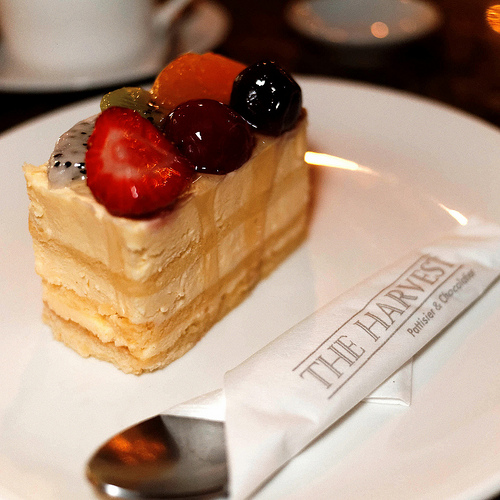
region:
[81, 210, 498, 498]
The silver spoon is next to the dessert.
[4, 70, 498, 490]
The dessert is on the white plate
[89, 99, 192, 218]
There are strawberries on top of the dessert.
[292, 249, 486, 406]
The Harvest is the name of the restaraunt.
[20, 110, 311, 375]
The dessert is made from ice cream.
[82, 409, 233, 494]
The bowl of the spoon is silver.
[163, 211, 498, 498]
The napkin is white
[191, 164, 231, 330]
The is fruit juices running down the side of the dessert.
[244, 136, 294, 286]
There are fruit juices running down the side of the dessert.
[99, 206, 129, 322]
There are fruit juices running down the side of the dessert.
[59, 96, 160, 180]
The kiwi on the piece of cake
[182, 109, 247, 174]
The cherry on the piece of cake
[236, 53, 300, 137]
The blue berry on the piece of cake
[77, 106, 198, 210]
The strawberry on the piece of cake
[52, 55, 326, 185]
The mixed fruit on the piece of cake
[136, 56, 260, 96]
The piece of orange on the cake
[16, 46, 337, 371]
A piece of cake with the fruit on it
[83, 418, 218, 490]
The tip of the spooon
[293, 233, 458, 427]
The label on the napkins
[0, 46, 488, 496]
A white plate with the cake and spoon on it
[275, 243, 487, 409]
Resturant logo on the napkin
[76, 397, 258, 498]
spoon wrapped in the white napkin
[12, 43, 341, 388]
Mini piece of dessert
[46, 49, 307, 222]
Fruit on top of the dessert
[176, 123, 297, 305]
Liquid dripping down the dessert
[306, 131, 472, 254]
Light shining off the plate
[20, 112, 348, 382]
Dessert is in layers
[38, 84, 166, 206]
Kiwi slices on top of the dessert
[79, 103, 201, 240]
a cut strawberry on the dessert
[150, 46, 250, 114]
A Juicy slice of an mardarin orange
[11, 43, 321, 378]
fruit on the cake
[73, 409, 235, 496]
head of the spoon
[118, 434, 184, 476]
reflection in the spoon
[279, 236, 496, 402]
words on the napkin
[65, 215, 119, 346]
layers on the cake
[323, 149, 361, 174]
shiny spot on the plate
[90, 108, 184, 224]
strawberry on the cake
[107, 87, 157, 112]
kiwi on the cake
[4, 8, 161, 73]
coffee mug in the background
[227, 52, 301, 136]
black raspberry on the cake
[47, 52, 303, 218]
the pieces of various fruit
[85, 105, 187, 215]
the piece of strawberry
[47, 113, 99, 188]
the piece of dragonfruit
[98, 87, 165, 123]
the piece of kiwi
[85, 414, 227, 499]
the top of the spoon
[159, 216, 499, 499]
the napkin wrapped around the spoon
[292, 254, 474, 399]
the print on the napkin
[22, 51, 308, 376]
the desert on the plate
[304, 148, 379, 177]
the reflection on the plate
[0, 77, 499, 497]
the white plate under the food